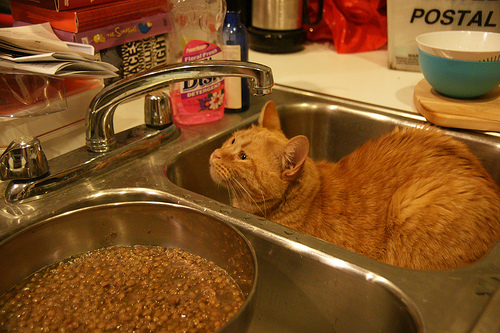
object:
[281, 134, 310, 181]
ear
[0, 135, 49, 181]
knob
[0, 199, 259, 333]
plate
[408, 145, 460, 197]
ground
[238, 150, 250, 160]
eye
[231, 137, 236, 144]
eye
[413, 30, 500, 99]
plate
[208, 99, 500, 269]
cat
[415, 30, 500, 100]
blue bowl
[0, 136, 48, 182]
opener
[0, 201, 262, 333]
bowl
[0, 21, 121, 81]
paper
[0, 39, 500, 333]
sink table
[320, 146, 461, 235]
fur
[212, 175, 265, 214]
whiskers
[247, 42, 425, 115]
chopping board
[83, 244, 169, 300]
beans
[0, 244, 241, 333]
water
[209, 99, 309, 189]
head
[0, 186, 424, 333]
sink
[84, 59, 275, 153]
faucet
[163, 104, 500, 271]
sink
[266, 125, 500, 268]
body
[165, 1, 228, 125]
bottle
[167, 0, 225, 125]
dish detergent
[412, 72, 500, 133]
board